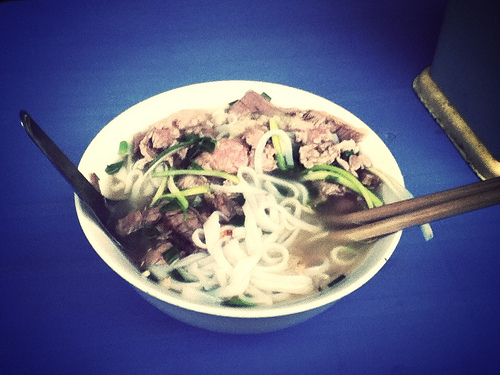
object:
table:
[1, 0, 499, 375]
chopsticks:
[315, 150, 500, 242]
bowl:
[72, 78, 409, 319]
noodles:
[108, 123, 368, 285]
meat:
[142, 126, 246, 234]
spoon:
[15, 102, 191, 277]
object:
[403, 66, 499, 173]